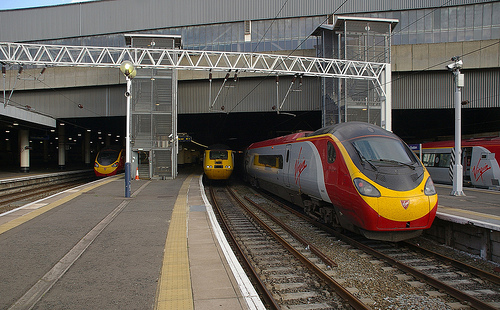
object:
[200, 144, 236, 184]
train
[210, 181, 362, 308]
track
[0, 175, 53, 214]
track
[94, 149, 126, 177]
train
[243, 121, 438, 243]
train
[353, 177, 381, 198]
headlights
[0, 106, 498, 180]
tunnel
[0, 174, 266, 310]
platform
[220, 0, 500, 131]
electrical wires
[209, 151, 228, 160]
windshield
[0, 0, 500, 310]
side of train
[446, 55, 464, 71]
camera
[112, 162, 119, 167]
headlights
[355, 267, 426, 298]
gravel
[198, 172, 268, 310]
line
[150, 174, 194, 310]
line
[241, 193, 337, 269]
line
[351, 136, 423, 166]
windshield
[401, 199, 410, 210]
symbol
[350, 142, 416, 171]
windshield wiper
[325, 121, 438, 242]
front of train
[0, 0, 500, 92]
bridge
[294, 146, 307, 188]
words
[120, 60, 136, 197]
lights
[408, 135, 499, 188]
train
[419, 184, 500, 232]
platform